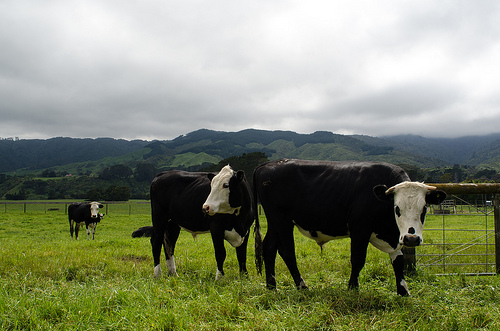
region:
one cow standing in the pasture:
[251, 140, 454, 320]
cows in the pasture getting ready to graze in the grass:
[17, 128, 438, 292]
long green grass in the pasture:
[16, 245, 142, 317]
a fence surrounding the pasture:
[3, 186, 67, 233]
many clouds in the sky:
[271, 13, 492, 125]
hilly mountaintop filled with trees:
[141, 122, 471, 160]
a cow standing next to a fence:
[251, 151, 491, 321]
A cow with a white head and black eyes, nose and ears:
[361, 161, 453, 261]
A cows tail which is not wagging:
[245, 149, 265, 276]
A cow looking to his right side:
[193, 127, 256, 231]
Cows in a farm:
[50, 148, 458, 301]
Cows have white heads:
[50, 147, 262, 299]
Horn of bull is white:
[375, 175, 430, 195]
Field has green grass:
[3, 194, 488, 321]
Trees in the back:
[0, 117, 499, 208]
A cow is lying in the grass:
[123, 220, 170, 240]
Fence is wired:
[423, 177, 499, 289]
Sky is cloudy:
[3, 5, 499, 140]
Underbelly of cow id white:
[183, 226, 247, 244]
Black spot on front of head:
[407, 219, 418, 236]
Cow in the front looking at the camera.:
[255, 165, 470, 297]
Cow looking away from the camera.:
[194, 159, 254, 249]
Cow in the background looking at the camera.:
[63, 190, 105, 238]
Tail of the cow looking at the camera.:
[243, 200, 269, 289]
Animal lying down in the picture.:
[131, 216, 154, 246]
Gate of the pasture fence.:
[436, 210, 478, 279]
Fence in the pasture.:
[31, 197, 49, 222]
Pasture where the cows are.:
[51, 242, 127, 305]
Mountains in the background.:
[64, 136, 214, 156]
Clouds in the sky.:
[118, 35, 288, 87]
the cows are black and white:
[53, 180, 479, 320]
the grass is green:
[58, 285, 113, 308]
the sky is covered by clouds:
[139, 50, 206, 108]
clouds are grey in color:
[213, 70, 247, 123]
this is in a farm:
[13, 170, 459, 323]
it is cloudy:
[1, 14, 471, 328]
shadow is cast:
[297, 285, 357, 311]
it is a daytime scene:
[6, 32, 498, 326]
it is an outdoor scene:
[6, 32, 488, 322]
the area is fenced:
[13, 195, 60, 218]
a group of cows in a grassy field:
[30, 111, 437, 319]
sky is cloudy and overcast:
[64, 5, 459, 125]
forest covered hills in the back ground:
[48, 124, 432, 160]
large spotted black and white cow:
[251, 161, 436, 293]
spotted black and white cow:
[126, 155, 256, 277]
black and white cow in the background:
[57, 195, 107, 247]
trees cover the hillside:
[15, 138, 144, 193]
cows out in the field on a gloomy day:
[27, 12, 442, 282]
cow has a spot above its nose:
[397, 222, 431, 241]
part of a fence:
[443, 172, 496, 279]